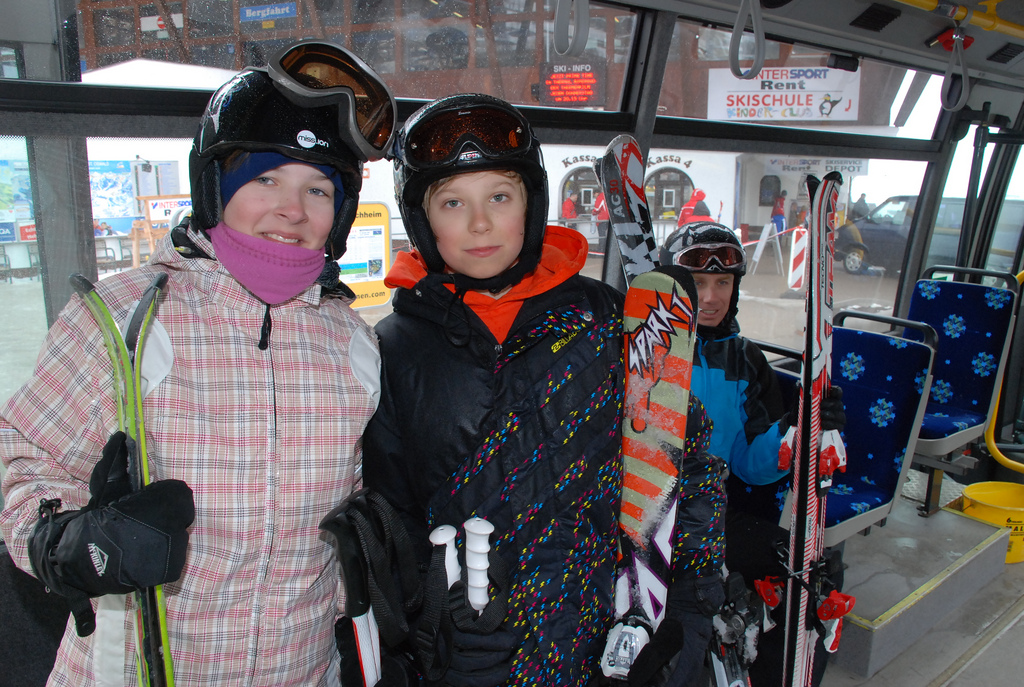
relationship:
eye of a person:
[253, 173, 331, 200] [0, 39, 400, 687]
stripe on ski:
[626, 395, 694, 441] [594, 261, 707, 683]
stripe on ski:
[618, 274, 698, 329] [594, 261, 707, 683]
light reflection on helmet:
[657, 215, 742, 254] [657, 215, 753, 324]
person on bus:
[363, 81, 733, 682] [7, 10, 993, 683]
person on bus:
[660, 221, 856, 687] [7, 10, 993, 683]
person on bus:
[0, 39, 400, 687] [7, 10, 993, 683]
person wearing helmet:
[669, 256, 784, 635] [649, 206, 740, 299]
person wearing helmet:
[362, 92, 730, 687] [396, 111, 561, 267]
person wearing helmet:
[61, 201, 340, 683] [167, 48, 366, 249]